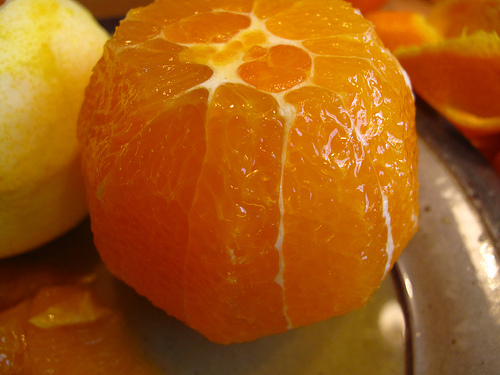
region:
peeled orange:
[79, 2, 423, 350]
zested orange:
[0, 0, 112, 265]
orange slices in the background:
[351, 0, 496, 140]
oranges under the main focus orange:
[1, 261, 176, 373]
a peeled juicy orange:
[77, 0, 419, 348]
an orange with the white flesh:
[1, 1, 85, 258]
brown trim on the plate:
[418, 124, 498, 264]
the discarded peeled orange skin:
[413, 0, 499, 157]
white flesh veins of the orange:
[276, 96, 300, 330]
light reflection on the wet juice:
[323, 77, 410, 225]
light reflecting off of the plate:
[440, 187, 499, 299]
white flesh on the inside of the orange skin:
[411, 26, 498, 56]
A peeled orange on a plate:
[78, 0, 421, 339]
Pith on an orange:
[186, 10, 295, 95]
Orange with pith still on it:
[5, 10, 104, 265]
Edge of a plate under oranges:
[411, 111, 498, 373]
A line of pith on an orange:
[276, 115, 288, 331]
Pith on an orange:
[379, 185, 394, 282]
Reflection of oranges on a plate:
[7, 265, 134, 372]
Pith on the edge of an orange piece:
[392, 25, 498, 52]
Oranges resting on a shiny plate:
[1, 2, 493, 374]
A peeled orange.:
[75, 0, 428, 348]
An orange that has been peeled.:
[75, 3, 421, 345]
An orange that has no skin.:
[75, 0, 420, 347]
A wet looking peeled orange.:
[82, 2, 419, 344]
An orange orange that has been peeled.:
[77, 2, 419, 342]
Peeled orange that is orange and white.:
[77, 0, 422, 340]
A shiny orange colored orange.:
[80, 3, 417, 348]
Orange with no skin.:
[75, 1, 420, 347]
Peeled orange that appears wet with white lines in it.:
[79, 2, 417, 347]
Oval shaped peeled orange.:
[77, 1, 419, 342]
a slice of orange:
[274, 75, 376, 357]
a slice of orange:
[191, 55, 278, 368]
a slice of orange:
[106, 61, 211, 372]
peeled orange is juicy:
[76, 0, 416, 341]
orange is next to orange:
[0, 0, 114, 258]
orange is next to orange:
[76, 0, 422, 343]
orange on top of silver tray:
[76, 0, 419, 343]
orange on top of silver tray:
[1, 0, 113, 256]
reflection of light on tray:
[380, 297, 405, 352]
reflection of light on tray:
[426, 163, 496, 324]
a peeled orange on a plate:
[75, 9, 422, 354]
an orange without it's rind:
[77, 6, 417, 343]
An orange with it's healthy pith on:
[0, 1, 114, 262]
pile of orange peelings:
[376, 0, 498, 167]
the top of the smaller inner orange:
[153, 6, 313, 98]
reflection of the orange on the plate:
[20, 266, 109, 349]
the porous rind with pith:
[369, 7, 499, 173]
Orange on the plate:
[72, 2, 427, 347]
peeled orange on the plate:
[80, 0, 426, 350]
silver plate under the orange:
[1, 74, 498, 373]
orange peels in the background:
[350, 0, 497, 152]